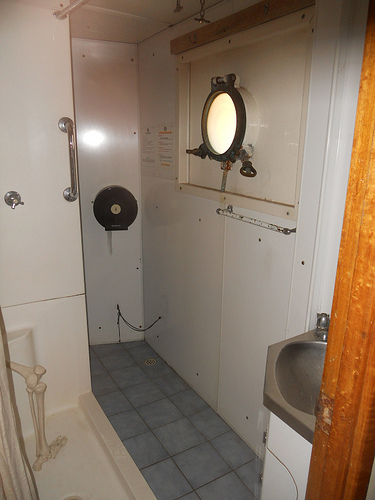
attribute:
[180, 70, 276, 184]
window — round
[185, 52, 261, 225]
frame — metal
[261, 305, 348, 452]
sink — silver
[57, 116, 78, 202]
handle — metal, safety handle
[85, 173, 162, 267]
dispenser — toilet paper dispenser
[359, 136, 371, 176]
door frame — wooden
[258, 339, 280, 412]
sink — metal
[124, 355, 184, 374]
drain — silver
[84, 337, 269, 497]
ground — tile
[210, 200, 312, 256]
towel bar — white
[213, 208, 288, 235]
paint — cracked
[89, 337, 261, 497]
grout — dark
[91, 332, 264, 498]
floor — grey